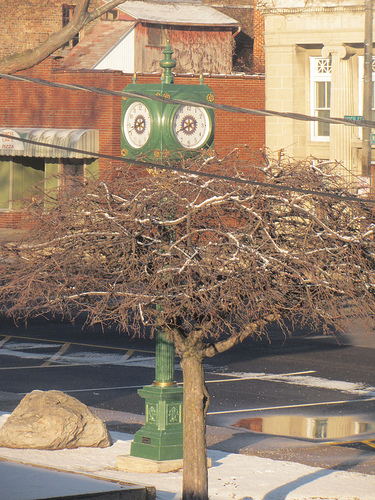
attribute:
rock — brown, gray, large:
[2, 384, 117, 456]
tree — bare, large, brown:
[3, 148, 373, 498]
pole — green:
[128, 165, 189, 461]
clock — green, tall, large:
[112, 93, 160, 154]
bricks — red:
[228, 130, 262, 144]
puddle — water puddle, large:
[230, 402, 373, 442]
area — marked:
[43, 358, 339, 424]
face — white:
[178, 103, 210, 147]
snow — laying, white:
[257, 463, 292, 484]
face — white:
[123, 104, 148, 142]